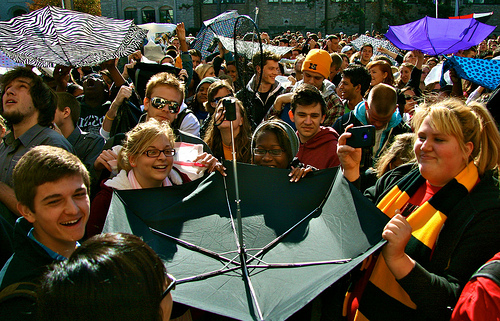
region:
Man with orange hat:
[283, 48, 343, 109]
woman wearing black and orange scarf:
[368, 110, 490, 313]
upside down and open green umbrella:
[101, 156, 388, 318]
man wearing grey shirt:
[0, 69, 76, 197]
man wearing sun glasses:
[127, 75, 200, 140]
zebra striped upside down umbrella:
[0, 2, 149, 69]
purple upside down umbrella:
[385, 15, 494, 55]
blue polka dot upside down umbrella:
[445, 55, 498, 91]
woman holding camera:
[340, 106, 495, 318]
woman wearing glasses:
[104, 126, 186, 196]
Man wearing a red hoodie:
[280, 90, 341, 172]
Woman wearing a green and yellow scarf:
[340, 111, 493, 316]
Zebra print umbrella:
[0, 6, 149, 80]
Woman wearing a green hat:
[238, 116, 315, 195]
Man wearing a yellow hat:
[280, 49, 339, 107]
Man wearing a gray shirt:
[0, 68, 70, 187]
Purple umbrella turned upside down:
[372, 2, 489, 62]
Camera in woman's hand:
[338, 122, 399, 210]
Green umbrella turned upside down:
[85, 117, 391, 319]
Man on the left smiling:
[5, 143, 98, 310]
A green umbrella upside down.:
[96, 92, 394, 319]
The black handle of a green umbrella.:
[212, 95, 237, 130]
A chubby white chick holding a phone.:
[335, 93, 496, 318]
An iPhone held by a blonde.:
[342, 121, 377, 150]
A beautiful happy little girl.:
[114, 115, 179, 182]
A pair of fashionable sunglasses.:
[149, 93, 181, 114]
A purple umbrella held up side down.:
[377, 12, 497, 59]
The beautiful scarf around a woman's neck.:
[340, 156, 480, 319]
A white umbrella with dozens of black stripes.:
[0, 0, 150, 69]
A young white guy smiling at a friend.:
[8, 140, 96, 244]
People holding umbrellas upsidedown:
[2, 4, 492, 316]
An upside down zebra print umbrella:
[0, 3, 154, 123]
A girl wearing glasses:
[124, 109, 194, 181]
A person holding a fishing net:
[218, 14, 287, 129]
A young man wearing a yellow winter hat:
[289, 36, 341, 91]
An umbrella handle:
[214, 71, 258, 274]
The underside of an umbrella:
[113, 184, 394, 320]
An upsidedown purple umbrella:
[381, 11, 499, 68]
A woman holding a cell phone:
[319, 71, 499, 251]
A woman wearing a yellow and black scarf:
[336, 84, 498, 309]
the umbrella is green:
[48, 31, 340, 307]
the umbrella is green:
[140, 74, 302, 309]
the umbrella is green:
[131, 61, 258, 229]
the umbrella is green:
[172, 156, 349, 318]